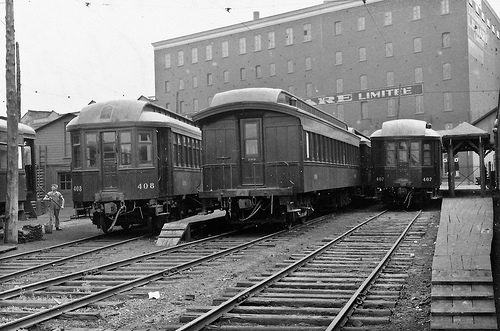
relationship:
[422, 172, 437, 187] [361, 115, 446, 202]
407 on train car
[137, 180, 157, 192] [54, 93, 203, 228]
408 on train car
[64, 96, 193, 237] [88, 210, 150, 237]
train car on wheels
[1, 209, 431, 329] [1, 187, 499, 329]
train tracks on ground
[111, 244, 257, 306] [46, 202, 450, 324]
dirt on ground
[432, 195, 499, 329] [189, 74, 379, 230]
staircase next to trains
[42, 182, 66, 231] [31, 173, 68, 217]
man holding stick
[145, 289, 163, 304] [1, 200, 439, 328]
paper on ground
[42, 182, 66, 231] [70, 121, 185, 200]
man washing train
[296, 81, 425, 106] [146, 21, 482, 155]
sign on building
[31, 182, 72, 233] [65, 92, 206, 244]
man standing by train